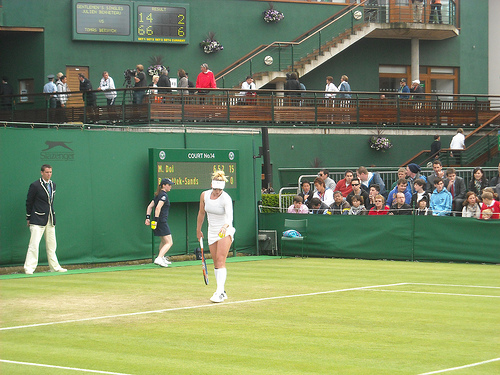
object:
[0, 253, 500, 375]
grass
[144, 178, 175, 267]
woman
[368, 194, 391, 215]
woman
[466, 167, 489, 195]
woman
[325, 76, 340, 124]
woman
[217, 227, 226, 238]
hand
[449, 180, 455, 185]
hand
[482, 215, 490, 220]
hand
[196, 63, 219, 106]
man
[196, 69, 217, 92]
top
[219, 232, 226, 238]
ball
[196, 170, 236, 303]
female player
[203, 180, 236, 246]
all white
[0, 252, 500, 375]
court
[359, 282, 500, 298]
stripe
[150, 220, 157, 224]
tennis ball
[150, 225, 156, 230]
tennis ball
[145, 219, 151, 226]
hand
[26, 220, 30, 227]
hand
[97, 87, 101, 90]
hand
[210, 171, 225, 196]
head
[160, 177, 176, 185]
hat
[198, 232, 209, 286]
racket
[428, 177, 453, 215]
person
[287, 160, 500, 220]
spectators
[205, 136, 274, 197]
floor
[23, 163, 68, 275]
man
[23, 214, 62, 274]
white pants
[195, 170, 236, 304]
match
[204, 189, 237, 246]
clothes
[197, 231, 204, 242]
hand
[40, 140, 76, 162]
logo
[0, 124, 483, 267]
wall